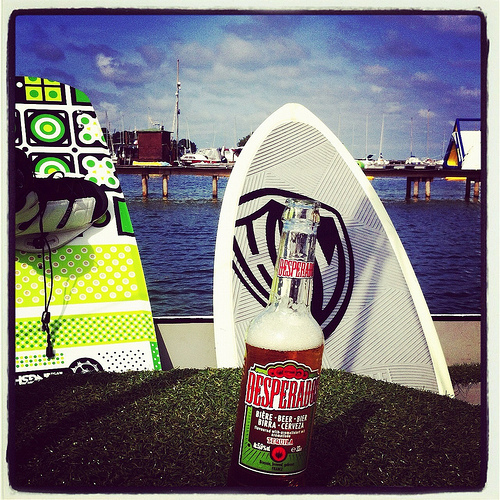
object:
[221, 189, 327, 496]
bottle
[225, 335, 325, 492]
tequila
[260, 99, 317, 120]
edge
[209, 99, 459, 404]
surfboard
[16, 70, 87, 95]
edge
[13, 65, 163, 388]
surfboard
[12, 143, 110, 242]
shoe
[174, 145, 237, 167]
boat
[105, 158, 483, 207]
pier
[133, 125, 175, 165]
building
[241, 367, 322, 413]
label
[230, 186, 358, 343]
logo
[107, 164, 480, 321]
water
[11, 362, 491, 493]
grass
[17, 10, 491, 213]
distance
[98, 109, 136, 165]
boat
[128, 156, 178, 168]
boat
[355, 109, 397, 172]
boat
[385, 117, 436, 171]
boat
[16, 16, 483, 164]
sky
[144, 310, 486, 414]
wall